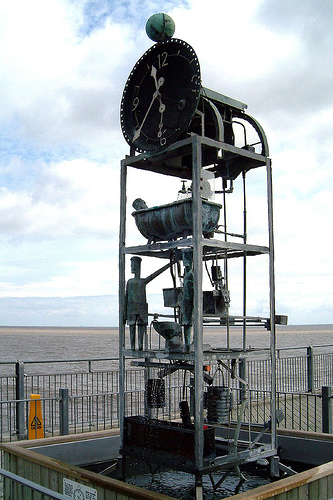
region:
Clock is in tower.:
[112, 35, 214, 138]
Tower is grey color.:
[107, 160, 285, 440]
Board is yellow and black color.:
[21, 391, 60, 446]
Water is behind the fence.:
[4, 329, 103, 405]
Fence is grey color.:
[8, 346, 328, 411]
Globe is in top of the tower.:
[130, 5, 185, 46]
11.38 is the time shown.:
[117, 46, 200, 141]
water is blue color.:
[6, 332, 111, 359]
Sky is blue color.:
[8, 134, 65, 169]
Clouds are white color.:
[71, 159, 124, 223]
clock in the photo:
[114, 42, 209, 143]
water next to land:
[37, 331, 84, 354]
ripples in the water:
[36, 341, 84, 356]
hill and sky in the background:
[27, 258, 82, 317]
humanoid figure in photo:
[102, 251, 177, 349]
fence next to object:
[54, 375, 110, 429]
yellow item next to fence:
[16, 386, 57, 434]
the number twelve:
[145, 46, 175, 76]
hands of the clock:
[117, 59, 185, 140]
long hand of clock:
[122, 82, 164, 147]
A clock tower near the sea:
[131, 19, 287, 487]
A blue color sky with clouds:
[22, 0, 115, 142]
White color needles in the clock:
[133, 59, 170, 141]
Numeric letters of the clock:
[117, 53, 198, 138]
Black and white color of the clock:
[114, 52, 210, 141]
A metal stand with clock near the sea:
[117, 162, 273, 471]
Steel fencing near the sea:
[3, 363, 112, 411]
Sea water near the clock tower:
[17, 329, 91, 347]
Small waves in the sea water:
[13, 330, 101, 353]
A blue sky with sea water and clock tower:
[30, 241, 320, 463]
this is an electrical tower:
[57, 6, 284, 411]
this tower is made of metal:
[117, 263, 255, 376]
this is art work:
[112, 255, 237, 331]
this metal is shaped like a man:
[115, 248, 175, 352]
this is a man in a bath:
[125, 173, 233, 242]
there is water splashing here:
[126, 369, 245, 476]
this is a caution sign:
[23, 378, 63, 448]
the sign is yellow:
[14, 392, 55, 438]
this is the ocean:
[18, 322, 95, 367]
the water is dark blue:
[26, 329, 101, 366]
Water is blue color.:
[13, 329, 88, 360]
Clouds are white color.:
[50, 139, 119, 206]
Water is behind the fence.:
[5, 316, 176, 413]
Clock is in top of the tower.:
[103, 36, 217, 143]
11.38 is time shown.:
[115, 42, 198, 138]